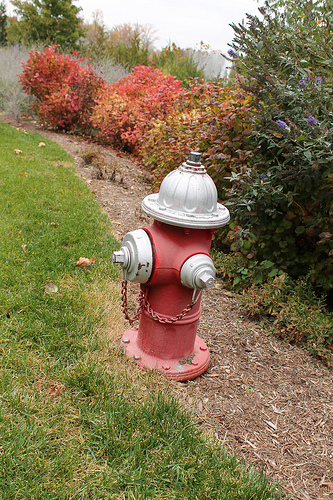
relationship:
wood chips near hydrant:
[216, 366, 322, 472] [93, 125, 225, 395]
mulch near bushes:
[86, 139, 139, 224] [57, 65, 265, 186]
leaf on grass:
[55, 248, 96, 278] [7, 177, 113, 319]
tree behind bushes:
[24, 1, 100, 57] [57, 65, 265, 186]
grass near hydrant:
[7, 177, 113, 319] [93, 125, 225, 395]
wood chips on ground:
[216, 366, 322, 472] [26, 161, 313, 478]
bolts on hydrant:
[117, 321, 214, 366] [93, 125, 225, 395]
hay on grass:
[29, 395, 219, 483] [7, 177, 113, 319]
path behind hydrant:
[62, 120, 145, 241] [93, 125, 225, 395]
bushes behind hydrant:
[57, 65, 265, 186] [93, 125, 225, 395]